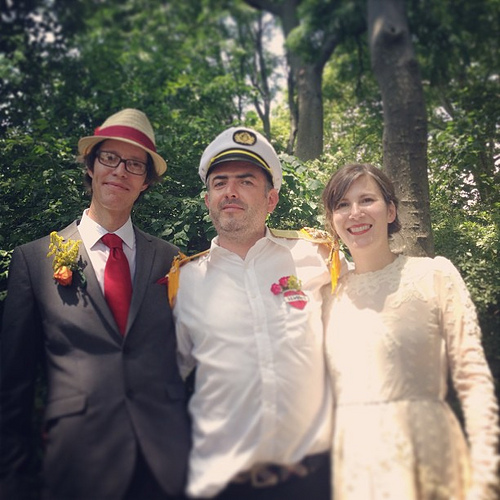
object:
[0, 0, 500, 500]
scene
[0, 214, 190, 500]
man in a suit coat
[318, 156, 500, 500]
woman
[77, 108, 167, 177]
hat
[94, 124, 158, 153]
red band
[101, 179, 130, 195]
smile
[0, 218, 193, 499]
suit jacket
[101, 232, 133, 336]
tie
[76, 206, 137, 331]
white shirt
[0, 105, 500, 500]
three people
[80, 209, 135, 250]
collar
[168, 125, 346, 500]
man in uniform top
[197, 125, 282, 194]
captains hat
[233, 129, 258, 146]
gold emblem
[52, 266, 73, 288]
red flower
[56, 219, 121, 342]
lapel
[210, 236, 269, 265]
open collar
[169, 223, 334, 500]
white shirt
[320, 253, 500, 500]
lace dress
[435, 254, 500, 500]
sleeve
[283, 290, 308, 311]
heart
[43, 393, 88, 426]
flap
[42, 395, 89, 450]
pocket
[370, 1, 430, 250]
tree trunk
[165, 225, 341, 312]
epaulets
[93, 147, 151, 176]
glasses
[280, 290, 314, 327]
pocket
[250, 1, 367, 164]
tree branch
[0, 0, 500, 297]
leaves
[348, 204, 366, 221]
nose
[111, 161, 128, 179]
nose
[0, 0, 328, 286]
leaves of tree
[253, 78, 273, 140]
tree stem